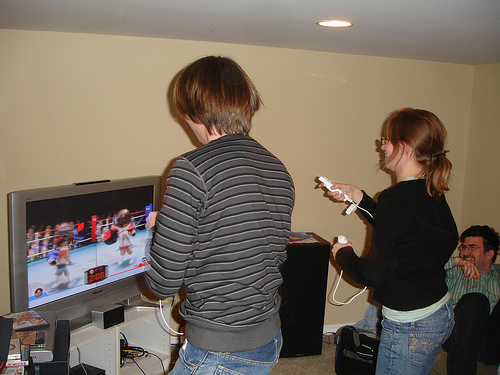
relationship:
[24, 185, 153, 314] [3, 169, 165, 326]
boxing game on television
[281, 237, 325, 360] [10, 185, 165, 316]
speakers next to television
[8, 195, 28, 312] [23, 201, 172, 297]
frame on television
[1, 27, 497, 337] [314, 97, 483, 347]
wall behind woman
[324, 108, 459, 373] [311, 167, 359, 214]
girl holding controller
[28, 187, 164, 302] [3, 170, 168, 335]
game playing on tv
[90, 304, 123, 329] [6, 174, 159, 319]
speaker in front of tv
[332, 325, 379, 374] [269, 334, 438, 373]
bag on floor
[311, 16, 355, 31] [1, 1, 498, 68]
light on ceiling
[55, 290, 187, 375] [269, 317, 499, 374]
tv stand on floor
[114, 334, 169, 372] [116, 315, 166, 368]
cords on shelf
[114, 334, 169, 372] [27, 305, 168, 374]
cords on tv stand